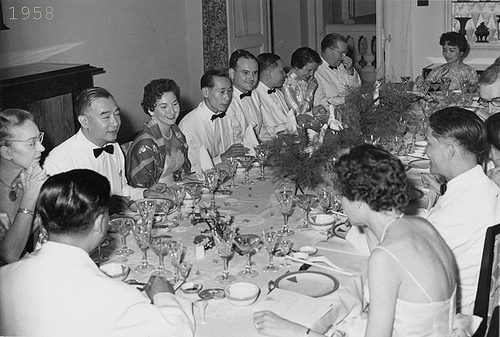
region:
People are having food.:
[12, 6, 488, 321]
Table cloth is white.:
[230, 182, 340, 308]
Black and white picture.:
[15, 30, 480, 320]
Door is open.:
[250, 6, 390, 106]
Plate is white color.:
[266, 255, 341, 305]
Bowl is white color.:
[215, 275, 265, 305]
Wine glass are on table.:
[186, 215, 281, 275]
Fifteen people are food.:
[10, 60, 480, 325]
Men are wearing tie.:
[63, 72, 358, 177]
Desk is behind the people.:
[8, 56, 126, 139]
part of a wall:
[128, 11, 181, 57]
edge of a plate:
[318, 276, 338, 298]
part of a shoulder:
[357, 245, 390, 298]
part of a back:
[398, 246, 427, 289]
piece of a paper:
[307, 299, 324, 315]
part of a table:
[216, 314, 230, 324]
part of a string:
[388, 248, 415, 295]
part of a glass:
[237, 231, 266, 265]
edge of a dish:
[312, 281, 333, 298]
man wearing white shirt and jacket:
[194, 115, 246, 140]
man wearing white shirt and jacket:
[262, 91, 294, 121]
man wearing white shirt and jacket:
[443, 187, 478, 242]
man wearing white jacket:
[21, 265, 98, 317]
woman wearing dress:
[368, 225, 450, 333]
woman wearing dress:
[143, 135, 182, 170]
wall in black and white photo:
[71, 10, 186, 62]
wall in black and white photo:
[386, 20, 425, 62]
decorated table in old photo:
[136, 196, 307, 267]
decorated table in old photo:
[373, 92, 422, 139]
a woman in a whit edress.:
[322, 143, 476, 334]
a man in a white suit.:
[0, 168, 189, 335]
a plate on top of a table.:
[273, 265, 338, 305]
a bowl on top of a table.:
[217, 278, 267, 315]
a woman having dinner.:
[123, 70, 194, 196]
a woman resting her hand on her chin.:
[0, 98, 59, 280]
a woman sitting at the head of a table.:
[405, 33, 484, 107]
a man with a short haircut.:
[220, 46, 274, 103]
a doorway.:
[303, 0, 383, 72]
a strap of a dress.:
[362, 247, 434, 299]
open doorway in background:
[316, 2, 382, 86]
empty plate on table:
[274, 268, 338, 297]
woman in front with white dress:
[331, 143, 476, 335]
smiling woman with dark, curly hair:
[127, 78, 194, 183]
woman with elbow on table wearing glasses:
[1, 107, 48, 258]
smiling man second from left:
[42, 86, 159, 201]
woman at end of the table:
[425, 30, 476, 92]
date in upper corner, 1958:
[8, 3, 54, 23]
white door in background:
[225, 2, 270, 60]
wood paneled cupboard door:
[26, 92, 76, 149]